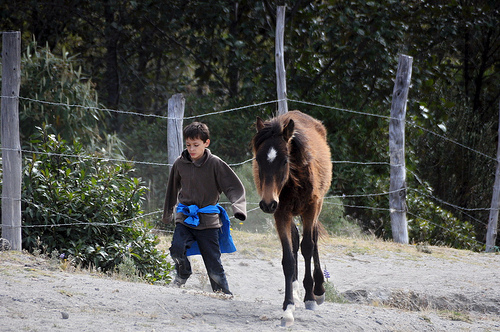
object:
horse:
[247, 110, 332, 328]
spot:
[266, 146, 278, 162]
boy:
[160, 121, 246, 295]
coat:
[175, 202, 237, 256]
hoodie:
[161, 148, 247, 230]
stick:
[1, 29, 23, 250]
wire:
[0, 94, 176, 123]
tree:
[70, 9, 139, 155]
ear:
[283, 119, 295, 142]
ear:
[256, 115, 266, 132]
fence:
[0, 28, 500, 252]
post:
[0, 30, 22, 252]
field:
[327, 233, 497, 328]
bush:
[44, 144, 162, 276]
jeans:
[168, 222, 232, 294]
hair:
[183, 122, 210, 144]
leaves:
[48, 167, 123, 203]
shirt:
[161, 148, 247, 230]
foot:
[279, 301, 295, 328]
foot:
[303, 294, 319, 309]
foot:
[313, 287, 326, 306]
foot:
[289, 277, 303, 292]